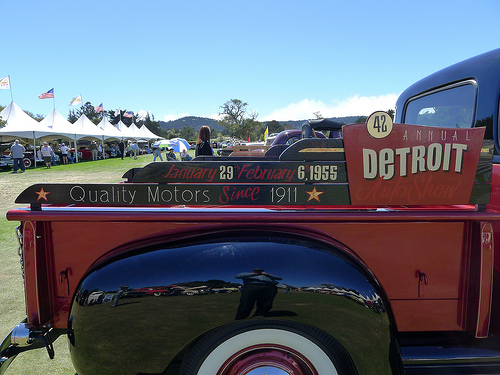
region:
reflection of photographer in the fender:
[234, 265, 281, 318]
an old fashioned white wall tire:
[179, 319, 350, 373]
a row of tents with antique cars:
[3, 100, 161, 169]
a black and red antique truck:
[4, 49, 498, 372]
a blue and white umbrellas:
[169, 137, 189, 160]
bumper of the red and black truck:
[0, 322, 58, 372]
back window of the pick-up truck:
[402, 79, 477, 129]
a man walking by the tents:
[8, 140, 23, 173]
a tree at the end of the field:
[219, 99, 256, 139]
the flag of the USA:
[37, 86, 58, 121]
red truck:
[24, 46, 496, 361]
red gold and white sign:
[341, 118, 469, 195]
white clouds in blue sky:
[24, 23, 65, 75]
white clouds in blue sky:
[161, 26, 202, 66]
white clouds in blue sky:
[250, 21, 282, 66]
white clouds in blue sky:
[341, 32, 372, 86]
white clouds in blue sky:
[82, 39, 153, 84]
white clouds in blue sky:
[215, 26, 295, 80]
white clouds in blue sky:
[310, 28, 357, 90]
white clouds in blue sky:
[201, 38, 258, 88]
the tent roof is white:
[4, 98, 50, 135]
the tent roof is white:
[35, 104, 97, 146]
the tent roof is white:
[76, 115, 113, 135]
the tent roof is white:
[83, 113, 124, 139]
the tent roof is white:
[101, 109, 144, 148]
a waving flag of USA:
[33, 82, 66, 116]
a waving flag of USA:
[88, 102, 114, 124]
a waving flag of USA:
[116, 104, 139, 133]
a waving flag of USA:
[44, 77, 62, 127]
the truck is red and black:
[23, 98, 481, 365]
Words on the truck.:
[60, 151, 307, 264]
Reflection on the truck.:
[165, 217, 414, 357]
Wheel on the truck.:
[172, 295, 297, 368]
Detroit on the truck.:
[341, 116, 491, 196]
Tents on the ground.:
[21, 79, 226, 204]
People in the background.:
[70, 100, 272, 190]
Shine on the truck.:
[69, 212, 390, 370]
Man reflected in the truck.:
[208, 249, 307, 327]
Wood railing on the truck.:
[101, 130, 367, 246]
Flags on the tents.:
[42, 75, 160, 115]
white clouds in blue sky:
[32, 21, 83, 83]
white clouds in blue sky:
[90, 25, 145, 61]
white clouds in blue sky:
[120, 23, 156, 55]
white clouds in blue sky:
[332, 12, 405, 121]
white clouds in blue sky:
[253, 29, 332, 76]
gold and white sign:
[350, 122, 468, 207]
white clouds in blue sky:
[56, 19, 118, 68]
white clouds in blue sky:
[163, 38, 218, 91]